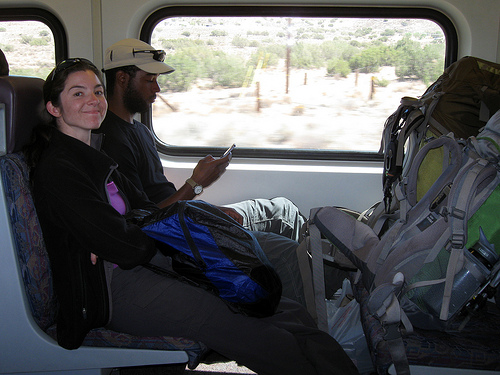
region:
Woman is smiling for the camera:
[37, 50, 359, 374]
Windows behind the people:
[0, 4, 468, 174]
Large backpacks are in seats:
[361, 57, 498, 333]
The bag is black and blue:
[140, 191, 280, 329]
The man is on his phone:
[92, 37, 314, 327]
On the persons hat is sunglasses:
[101, 37, 176, 77]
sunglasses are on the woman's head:
[25, 58, 107, 151]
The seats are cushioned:
[1, 76, 213, 371]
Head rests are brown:
[0, 67, 59, 154]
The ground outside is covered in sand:
[145, 11, 449, 169]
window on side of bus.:
[216, 46, 349, 118]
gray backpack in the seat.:
[417, 215, 448, 264]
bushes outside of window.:
[332, 42, 424, 67]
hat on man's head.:
[112, 47, 158, 70]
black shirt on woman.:
[57, 162, 105, 234]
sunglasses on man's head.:
[130, 46, 167, 63]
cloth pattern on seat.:
[10, 167, 47, 307]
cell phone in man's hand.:
[216, 143, 236, 167]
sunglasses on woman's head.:
[54, 56, 98, 68]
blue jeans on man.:
[243, 204, 299, 226]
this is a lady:
[37, 58, 106, 277]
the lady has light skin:
[67, 103, 79, 117]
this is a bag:
[171, 201, 247, 277]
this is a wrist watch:
[191, 178, 199, 191]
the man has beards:
[128, 97, 142, 115]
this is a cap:
[116, 46, 141, 59]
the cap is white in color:
[143, 62, 163, 71]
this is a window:
[170, 9, 360, 146]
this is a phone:
[222, 145, 236, 152]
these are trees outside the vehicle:
[216, 26, 428, 76]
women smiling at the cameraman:
[35, 49, 120, 160]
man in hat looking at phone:
[104, 35, 237, 192]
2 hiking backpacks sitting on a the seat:
[392, 54, 499, 323]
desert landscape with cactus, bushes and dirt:
[178, 18, 381, 157]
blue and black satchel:
[138, 197, 308, 326]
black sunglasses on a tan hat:
[103, 22, 176, 81]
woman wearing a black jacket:
[27, 55, 159, 332]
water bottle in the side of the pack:
[401, 210, 499, 357]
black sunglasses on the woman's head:
[21, 41, 116, 185]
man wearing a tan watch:
[153, 156, 244, 225]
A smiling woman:
[31, 24, 123, 325]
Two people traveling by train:
[20, 23, 229, 296]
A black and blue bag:
[124, 172, 302, 331]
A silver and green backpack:
[346, 54, 495, 353]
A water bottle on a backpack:
[410, 215, 495, 348]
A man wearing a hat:
[100, 21, 172, 181]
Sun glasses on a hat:
[92, 31, 179, 73]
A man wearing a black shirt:
[100, 30, 185, 191]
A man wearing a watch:
[97, 21, 227, 201]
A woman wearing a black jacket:
[38, 56, 147, 310]